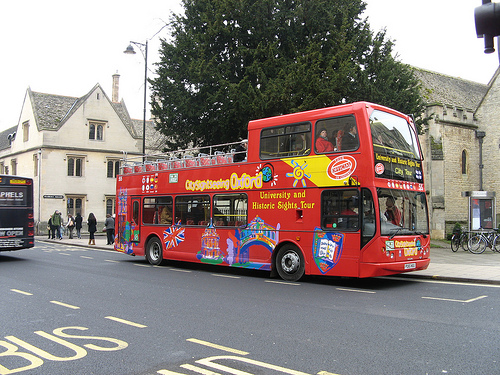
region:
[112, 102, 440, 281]
Double-decker tour bus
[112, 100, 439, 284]
Red tour bus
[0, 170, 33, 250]
Black bus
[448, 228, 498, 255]
Bicycles parked on sidewalk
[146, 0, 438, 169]
Large green tree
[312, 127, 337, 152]
Tourist inside bus wearing red jacket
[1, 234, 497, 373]
Street with bus lanes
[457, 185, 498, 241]
Information display on sidewalk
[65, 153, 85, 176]
Window on building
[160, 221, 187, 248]
Drawing of British flag on side of tour bus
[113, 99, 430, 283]
a red tourist bus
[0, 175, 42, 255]
a black bus on street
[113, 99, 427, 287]
a double decker bus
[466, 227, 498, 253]
a parked bicycle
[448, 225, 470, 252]
a parked bicycle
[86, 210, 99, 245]
a pedestrian on sidewalk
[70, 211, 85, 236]
a pedestrian on sidewalk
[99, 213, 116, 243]
a pedestrian on sidewalk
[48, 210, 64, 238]
a pedestrian on sidewalk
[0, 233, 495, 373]
a paved city street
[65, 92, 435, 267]
the bus is red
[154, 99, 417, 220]
the bus has passengers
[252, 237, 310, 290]
the wheel is black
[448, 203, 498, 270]
bikes are parked on the sidewalk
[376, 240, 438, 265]
the headlights are off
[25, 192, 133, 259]
the people are walking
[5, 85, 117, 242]
the building is white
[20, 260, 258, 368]
the lines in the street are white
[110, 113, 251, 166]
the top of the bus is open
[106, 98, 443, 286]
double decker bus with open top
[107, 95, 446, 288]
tall red bus with two levels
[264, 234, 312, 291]
large rubber tire on bus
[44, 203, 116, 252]
group of people walking on a sidewalk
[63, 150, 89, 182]
window with two separate panes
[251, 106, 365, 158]
heavily tinted bus windows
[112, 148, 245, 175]
row of seats on open top level of bus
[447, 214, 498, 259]
bicycles by the sidewalk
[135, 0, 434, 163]
large tree growing by sidewalk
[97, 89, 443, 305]
bus driving by tall tree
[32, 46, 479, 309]
a bus in the city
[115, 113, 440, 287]
passengers can be seen on the bus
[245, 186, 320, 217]
this is a tour bus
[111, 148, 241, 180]
seats along the top of the bus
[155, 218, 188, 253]
this bus is in the U.K.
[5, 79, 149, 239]
a building on the street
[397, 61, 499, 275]
a building next to the bus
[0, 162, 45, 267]
a black bus on the street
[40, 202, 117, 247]
people on the block